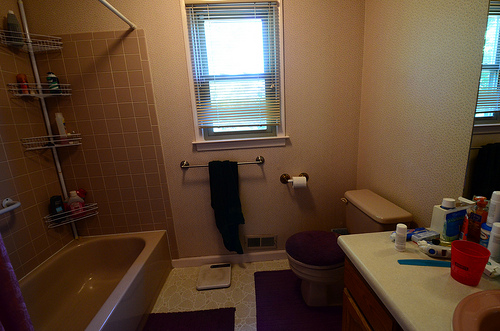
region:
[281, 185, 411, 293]
Brown toilet in the bathroom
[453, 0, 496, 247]
Mirror above the vanity in the bathroom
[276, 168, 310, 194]
Roll of toliet paper by the toilet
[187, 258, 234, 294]
Bathroom scale on the floor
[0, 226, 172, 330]
Brown bathtub to the right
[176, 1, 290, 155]
Window in the center of the bathroom wall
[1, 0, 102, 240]
Metal shower organizer above the bathtub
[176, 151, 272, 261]
Towel rack with a brown towel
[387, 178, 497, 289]
Various tolietries on the vanity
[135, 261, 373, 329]
Two brown rugs on the bathroom flloor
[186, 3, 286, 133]
open window blinds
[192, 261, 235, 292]
a white weight scale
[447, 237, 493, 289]
plastic red cup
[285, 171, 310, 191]
a roll of toilet paper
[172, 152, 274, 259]
towel hanging on a rack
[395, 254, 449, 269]
a light blue comb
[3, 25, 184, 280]
shower walls made of tile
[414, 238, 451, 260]
an electric thermometer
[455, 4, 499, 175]
reflection of window in mirror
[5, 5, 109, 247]
corner shower racks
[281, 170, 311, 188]
a white color napkin roll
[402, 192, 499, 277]
lot of things kept near the wash basin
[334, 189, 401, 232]
a sandle color flush tank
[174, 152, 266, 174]
hanger attached in the wall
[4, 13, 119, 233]
a steel rack attached in the wall with some things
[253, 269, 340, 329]
floor mat in the rest room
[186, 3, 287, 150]
window of the toilet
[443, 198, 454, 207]
top of the bottle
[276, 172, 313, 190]
napkin roll with the hanger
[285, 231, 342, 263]
purple toilet seat cover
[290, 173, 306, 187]
toilet paper on holder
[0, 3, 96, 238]
shower rack with shelves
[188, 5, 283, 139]
single bathroom window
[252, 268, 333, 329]
purple toilet rug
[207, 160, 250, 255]
black bath towel hanging from rack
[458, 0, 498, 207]
part of mirror on wall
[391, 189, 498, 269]
bathroom items on counter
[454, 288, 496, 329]
part of tan sink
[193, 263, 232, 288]
scale on floor of bathroom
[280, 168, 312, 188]
toilet paper holder attached to wall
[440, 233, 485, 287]
red cup on kitchen counter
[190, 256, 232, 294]
white scale on bathroom floor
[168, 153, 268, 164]
silver towel bar attached to wall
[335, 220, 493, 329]
white counter bathroom sink is on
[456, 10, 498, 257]
mirror above bathroom sink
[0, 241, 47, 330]
shower curtain pulled back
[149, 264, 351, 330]
rugs on bathroom floor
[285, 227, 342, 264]
cover on toilet lid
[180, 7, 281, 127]
window with blinds covering them